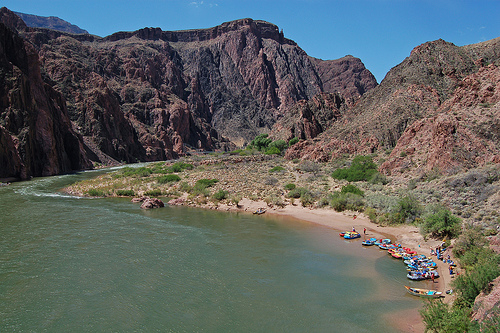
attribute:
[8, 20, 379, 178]
cliff — large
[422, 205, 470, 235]
bush — fat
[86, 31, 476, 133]
mountains — dark brown